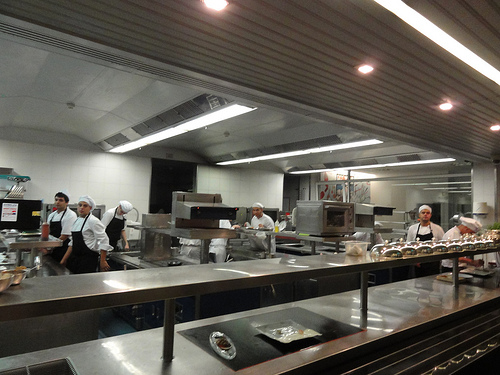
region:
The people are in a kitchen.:
[0, 128, 490, 313]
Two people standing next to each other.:
[30, 185, 125, 266]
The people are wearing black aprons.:
[31, 185, 121, 265]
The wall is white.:
[46, 155, 143, 190]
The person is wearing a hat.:
[65, 192, 95, 222]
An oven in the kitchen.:
[285, 190, 362, 245]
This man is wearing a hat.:
[391, 196, 451, 225]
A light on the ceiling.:
[100, 100, 256, 160]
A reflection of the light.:
[83, 267, 145, 293]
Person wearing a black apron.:
[398, 214, 448, 246]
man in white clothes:
[397, 196, 453, 251]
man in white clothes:
[237, 194, 284, 254]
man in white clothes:
[57, 190, 111, 276]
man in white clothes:
[95, 188, 146, 254]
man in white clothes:
[44, 183, 84, 261]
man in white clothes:
[424, 213, 489, 270]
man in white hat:
[239, 196, 279, 256]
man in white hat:
[94, 191, 143, 251]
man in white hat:
[50, 195, 118, 273]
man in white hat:
[431, 207, 492, 259]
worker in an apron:
[60, 195, 115, 274]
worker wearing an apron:
[43, 190, 75, 247]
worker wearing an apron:
[406, 201, 444, 247]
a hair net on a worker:
[62, 196, 110, 268]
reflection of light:
[93, 275, 134, 302]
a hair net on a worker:
[405, 203, 445, 240]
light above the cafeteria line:
[355, 63, 372, 76]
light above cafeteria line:
[438, 96, 448, 113]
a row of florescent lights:
[106, 96, 251, 156]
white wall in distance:
[197, 165, 282, 212]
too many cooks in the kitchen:
[41, 182, 491, 342]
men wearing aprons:
[49, 192, 136, 261]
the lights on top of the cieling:
[166, 3, 498, 154]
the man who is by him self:
[234, 194, 290, 235]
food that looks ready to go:
[211, 312, 335, 357]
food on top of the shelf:
[349, 231, 498, 252]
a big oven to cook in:
[275, 182, 382, 248]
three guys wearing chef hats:
[56, 183, 166, 211]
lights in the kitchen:
[119, 106, 387, 177]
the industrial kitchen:
[8, 29, 461, 350]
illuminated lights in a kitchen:
[347, 51, 499, 141]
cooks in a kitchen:
[40, 184, 142, 270]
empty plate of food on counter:
[249, 310, 329, 357]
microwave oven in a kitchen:
[293, 191, 365, 241]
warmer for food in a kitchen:
[167, 186, 247, 245]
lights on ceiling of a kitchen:
[79, 87, 270, 155]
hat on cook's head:
[76, 191, 98, 209]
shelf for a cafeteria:
[372, 313, 498, 373]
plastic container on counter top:
[341, 234, 373, 259]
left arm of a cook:
[97, 248, 116, 273]